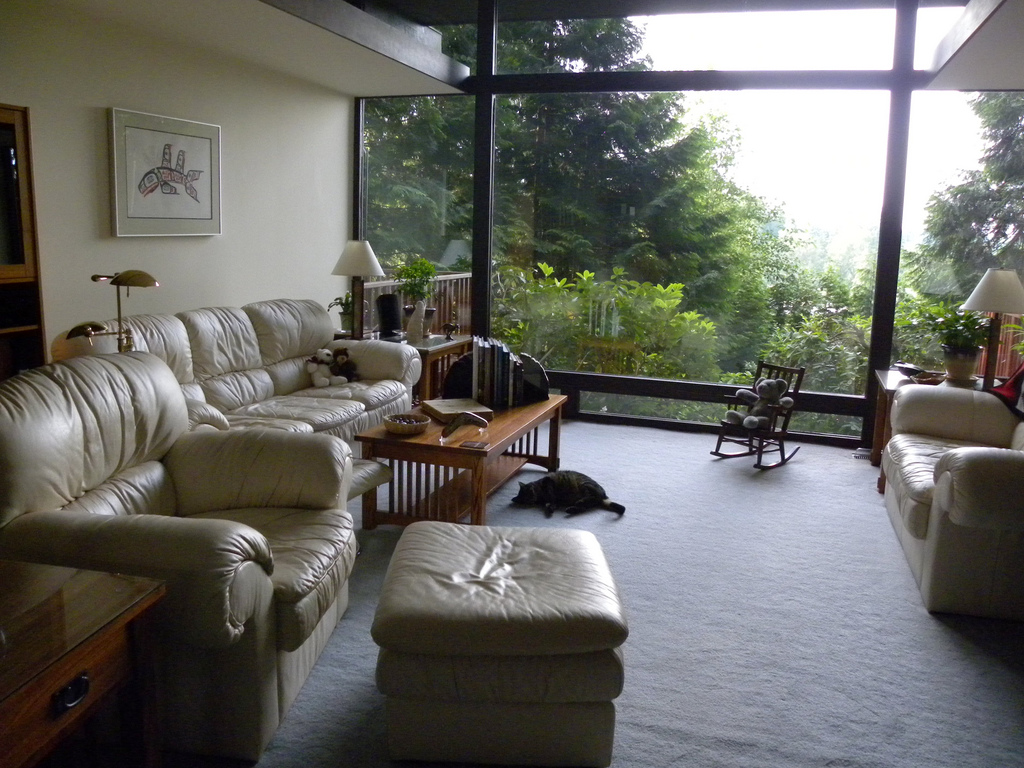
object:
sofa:
[50, 298, 423, 463]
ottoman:
[370, 521, 628, 768]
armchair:
[0, 351, 362, 767]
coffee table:
[353, 393, 567, 529]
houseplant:
[920, 307, 1007, 386]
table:
[870, 370, 1004, 467]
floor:
[255, 419, 1022, 768]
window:
[471, 71, 911, 449]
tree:
[550, 17, 744, 293]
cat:
[510, 470, 623, 515]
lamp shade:
[329, 240, 386, 340]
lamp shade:
[961, 268, 1024, 391]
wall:
[0, 0, 355, 364]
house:
[0, 0, 1022, 768]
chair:
[710, 362, 806, 471]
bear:
[725, 377, 794, 428]